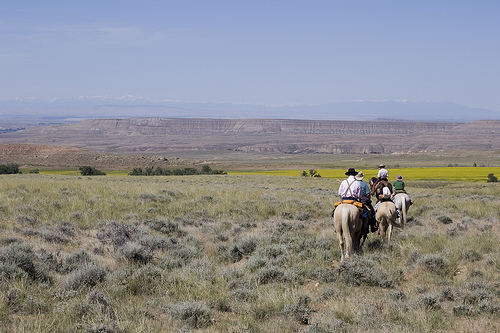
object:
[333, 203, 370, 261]
horse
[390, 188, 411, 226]
horse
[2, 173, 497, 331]
trail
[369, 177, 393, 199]
horse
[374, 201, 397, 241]
horse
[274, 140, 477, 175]
trail